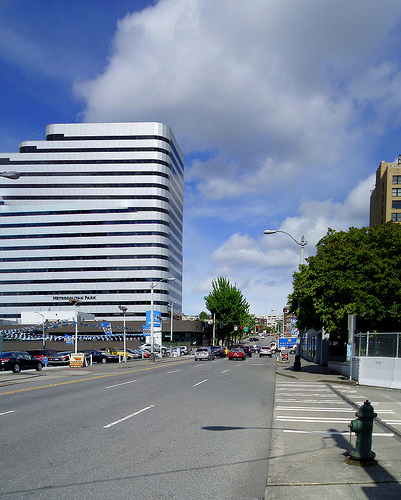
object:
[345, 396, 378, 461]
fire hydrant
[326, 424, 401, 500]
shadow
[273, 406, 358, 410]
crosswalk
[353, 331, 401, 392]
fence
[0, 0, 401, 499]
background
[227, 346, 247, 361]
car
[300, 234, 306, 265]
light pole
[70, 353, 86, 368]
sign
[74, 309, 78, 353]
pole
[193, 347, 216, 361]
cars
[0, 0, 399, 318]
sky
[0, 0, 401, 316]
clouds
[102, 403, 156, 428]
lines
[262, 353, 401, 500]
sidewalk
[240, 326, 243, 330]
light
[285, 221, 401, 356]
trees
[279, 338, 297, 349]
sign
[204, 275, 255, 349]
tree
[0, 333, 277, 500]
road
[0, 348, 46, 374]
car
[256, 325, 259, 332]
traffic lights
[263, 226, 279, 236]
street light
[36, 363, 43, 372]
wheel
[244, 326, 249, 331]
sign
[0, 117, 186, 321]
honda dealership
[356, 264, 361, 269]
leaves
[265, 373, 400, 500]
concrete